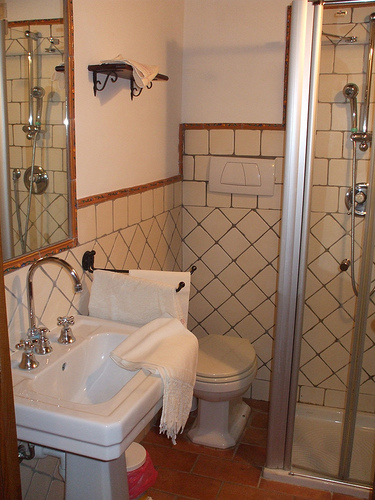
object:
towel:
[109, 311, 199, 445]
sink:
[9, 312, 163, 499]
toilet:
[187, 333, 259, 450]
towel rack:
[81, 246, 197, 294]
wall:
[1, 0, 184, 500]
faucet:
[25, 256, 83, 336]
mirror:
[0, 0, 70, 263]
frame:
[0, 0, 79, 275]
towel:
[99, 52, 159, 89]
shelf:
[86, 62, 169, 102]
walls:
[178, 0, 373, 419]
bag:
[127, 449, 158, 500]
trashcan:
[124, 442, 150, 499]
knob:
[15, 335, 41, 371]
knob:
[56, 314, 77, 346]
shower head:
[342, 82, 361, 142]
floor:
[133, 395, 374, 499]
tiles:
[209, 126, 236, 158]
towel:
[88, 271, 184, 330]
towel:
[127, 267, 191, 331]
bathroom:
[0, 0, 372, 497]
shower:
[263, 0, 373, 500]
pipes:
[42, 442, 66, 470]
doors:
[284, 0, 375, 486]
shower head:
[30, 86, 46, 128]